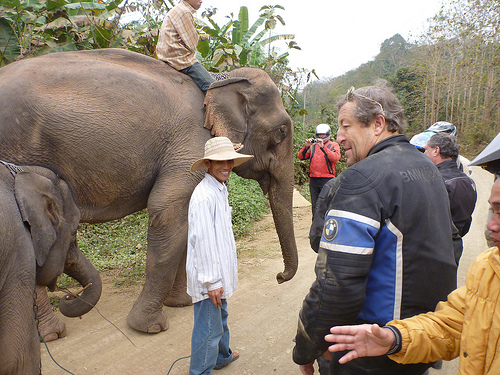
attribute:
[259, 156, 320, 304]
trunk — long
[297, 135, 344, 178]
coat — red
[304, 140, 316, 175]
stripe — black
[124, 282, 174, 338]
foot — large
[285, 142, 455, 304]
jacket — blue, whitte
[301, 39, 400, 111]
hill — tree covered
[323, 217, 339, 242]
symbol — BMW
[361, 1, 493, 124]
trees — clump, skinny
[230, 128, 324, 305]
trunk — long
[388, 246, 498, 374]
coat — yellow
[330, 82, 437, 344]
coat — black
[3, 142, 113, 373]
elephant — small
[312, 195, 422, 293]
design — blue and white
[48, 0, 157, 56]
leaves — big, green